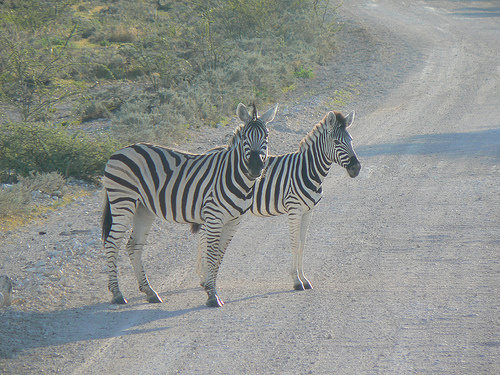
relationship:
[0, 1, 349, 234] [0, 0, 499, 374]
brush beside dirt road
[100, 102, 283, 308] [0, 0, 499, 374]
animal on dirt road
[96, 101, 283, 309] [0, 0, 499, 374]
animal on dirt road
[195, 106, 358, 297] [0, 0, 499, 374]
zebra on dirt road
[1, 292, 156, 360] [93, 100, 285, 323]
shadow of zebra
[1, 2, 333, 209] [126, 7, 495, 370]
brush on side of road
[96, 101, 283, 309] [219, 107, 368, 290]
animal standing side by side with zebra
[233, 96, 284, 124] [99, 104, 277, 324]
ears of animal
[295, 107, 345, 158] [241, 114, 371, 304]
mane of animal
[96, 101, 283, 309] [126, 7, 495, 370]
animal standing on edge of a road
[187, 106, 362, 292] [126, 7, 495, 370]
zebra standing on edge of a road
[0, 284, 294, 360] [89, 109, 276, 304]
shadow of zebra